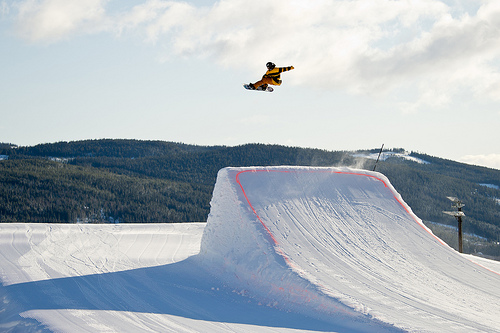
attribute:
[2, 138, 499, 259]
hillside — tree-covered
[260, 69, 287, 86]
jacket — yellow, black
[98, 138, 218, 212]
hills — tree-covered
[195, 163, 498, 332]
ramp — snow-covered, snow-made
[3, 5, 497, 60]
clouds — white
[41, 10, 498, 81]
clouds — white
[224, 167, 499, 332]
ramp — snow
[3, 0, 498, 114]
clouds — white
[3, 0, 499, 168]
sky — blue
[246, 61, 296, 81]
jacket — yellow, black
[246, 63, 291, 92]
snowboarder — airborne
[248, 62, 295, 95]
person — doing trick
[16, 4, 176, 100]
sky — cloudy, grey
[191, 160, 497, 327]
snow ramp — tall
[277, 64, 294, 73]
arm — extended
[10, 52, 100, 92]
sky — blue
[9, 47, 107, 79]
sky — blue